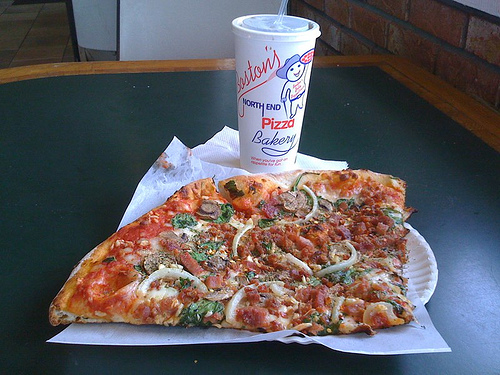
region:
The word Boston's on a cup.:
[218, 45, 283, 100]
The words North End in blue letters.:
[239, 92, 284, 115]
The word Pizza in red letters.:
[255, 111, 302, 134]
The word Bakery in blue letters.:
[247, 130, 301, 158]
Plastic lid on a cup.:
[231, 7, 322, 45]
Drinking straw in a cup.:
[269, 2, 294, 22]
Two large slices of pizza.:
[41, 130, 451, 358]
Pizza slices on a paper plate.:
[34, 149, 476, 360]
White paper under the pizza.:
[53, 138, 461, 373]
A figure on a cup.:
[268, 42, 321, 119]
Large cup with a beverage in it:
[226, 7, 316, 172]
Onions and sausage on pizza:
[142, 253, 208, 297]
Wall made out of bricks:
[420, 6, 481, 86]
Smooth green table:
[26, 94, 113, 177]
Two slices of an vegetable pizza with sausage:
[38, 160, 415, 353]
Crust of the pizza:
[221, 170, 413, 190]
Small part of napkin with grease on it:
[148, 140, 193, 185]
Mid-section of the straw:
[270, 7, 290, 24]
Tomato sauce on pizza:
[131, 222, 161, 234]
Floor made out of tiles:
[11, 16, 58, 58]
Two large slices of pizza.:
[0, 165, 437, 373]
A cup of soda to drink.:
[222, 10, 344, 173]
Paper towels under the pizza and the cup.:
[54, 130, 441, 368]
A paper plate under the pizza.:
[130, 159, 446, 299]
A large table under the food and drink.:
[7, 60, 498, 326]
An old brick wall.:
[317, 5, 495, 43]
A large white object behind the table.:
[76, 0, 293, 74]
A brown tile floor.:
[0, 2, 72, 79]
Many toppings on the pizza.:
[178, 199, 382, 321]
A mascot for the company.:
[275, 50, 311, 124]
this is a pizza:
[141, 180, 398, 310]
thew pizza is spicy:
[151, 180, 398, 321]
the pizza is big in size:
[126, 180, 401, 322]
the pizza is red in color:
[176, 176, 401, 323]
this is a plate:
[417, 250, 432, 275]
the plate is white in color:
[419, 250, 432, 287]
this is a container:
[218, 24, 320, 154]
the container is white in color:
[216, 17, 326, 159]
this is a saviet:
[403, 334, 430, 352]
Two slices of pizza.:
[22, 125, 477, 370]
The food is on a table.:
[0, 51, 495, 366]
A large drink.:
[215, 10, 325, 171]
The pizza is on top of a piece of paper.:
[50, 152, 450, 362]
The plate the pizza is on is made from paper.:
[55, 145, 435, 345]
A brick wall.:
[295, 0, 496, 90]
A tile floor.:
[0, 0, 80, 70]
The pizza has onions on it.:
[85, 170, 425, 350]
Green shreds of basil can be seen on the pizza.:
[150, 175, 415, 345]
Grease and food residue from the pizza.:
[138, 135, 204, 187]